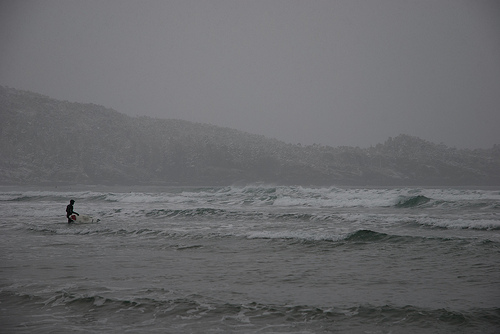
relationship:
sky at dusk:
[156, 47, 268, 77] [376, 120, 454, 133]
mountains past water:
[50, 114, 174, 150] [127, 192, 219, 205]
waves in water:
[258, 177, 457, 225] [127, 192, 219, 205]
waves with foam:
[258, 177, 457, 225] [132, 195, 189, 204]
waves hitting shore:
[258, 177, 457, 225] [96, 183, 191, 192]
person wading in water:
[63, 197, 85, 238] [127, 192, 219, 205]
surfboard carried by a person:
[68, 212, 94, 225] [63, 197, 85, 238]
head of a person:
[66, 198, 77, 207] [63, 197, 85, 238]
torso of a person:
[66, 204, 77, 214] [64, 199, 78, 227]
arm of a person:
[71, 208, 82, 217] [63, 197, 85, 238]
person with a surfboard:
[63, 197, 85, 238] [68, 212, 94, 225]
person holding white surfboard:
[63, 197, 85, 238] [68, 212, 94, 225]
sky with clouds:
[156, 47, 268, 77] [438, 37, 481, 104]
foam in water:
[132, 195, 189, 204] [127, 192, 219, 205]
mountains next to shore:
[50, 114, 174, 150] [96, 183, 191, 192]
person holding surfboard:
[63, 197, 85, 238] [68, 212, 94, 225]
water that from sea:
[127, 192, 219, 205] [317, 211, 411, 279]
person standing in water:
[63, 197, 85, 238] [127, 192, 219, 205]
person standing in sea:
[63, 197, 85, 238] [317, 211, 411, 279]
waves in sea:
[258, 177, 457, 225] [317, 211, 411, 279]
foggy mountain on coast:
[344, 97, 391, 112] [184, 175, 289, 188]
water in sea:
[127, 192, 219, 205] [317, 211, 411, 279]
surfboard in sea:
[68, 212, 94, 225] [317, 211, 411, 279]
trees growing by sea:
[392, 135, 444, 157] [317, 211, 411, 279]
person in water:
[63, 197, 85, 238] [127, 192, 219, 205]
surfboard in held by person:
[68, 212, 94, 225] [63, 197, 85, 238]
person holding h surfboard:
[63, 197, 85, 238] [68, 212, 94, 225]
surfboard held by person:
[68, 212, 94, 225] [63, 197, 85, 238]